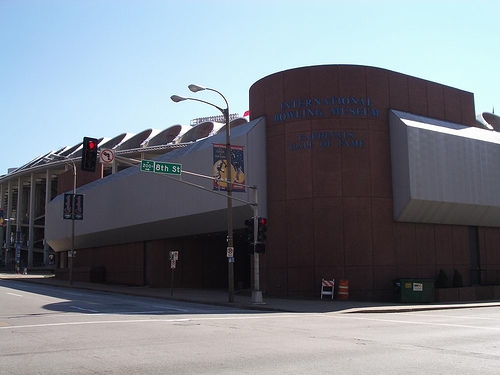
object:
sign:
[13, 240, 23, 257]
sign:
[163, 247, 180, 271]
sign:
[225, 245, 236, 265]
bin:
[390, 278, 435, 303]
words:
[364, 97, 374, 110]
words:
[329, 108, 381, 118]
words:
[286, 141, 317, 152]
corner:
[247, 63, 390, 301]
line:
[338, 198, 345, 265]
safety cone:
[334, 275, 351, 300]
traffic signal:
[257, 215, 267, 295]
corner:
[241, 291, 406, 313]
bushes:
[430, 265, 454, 290]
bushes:
[452, 257, 463, 286]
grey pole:
[250, 183, 267, 305]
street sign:
[96, 146, 116, 167]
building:
[247, 65, 500, 304]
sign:
[211, 142, 247, 193]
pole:
[224, 109, 239, 306]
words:
[297, 130, 355, 143]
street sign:
[140, 160, 185, 175]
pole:
[112, 157, 255, 193]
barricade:
[320, 276, 335, 302]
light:
[186, 83, 203, 93]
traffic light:
[82, 137, 102, 175]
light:
[257, 214, 268, 226]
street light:
[49, 154, 75, 286]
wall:
[405, 126, 499, 206]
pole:
[110, 159, 253, 209]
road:
[0, 280, 499, 374]